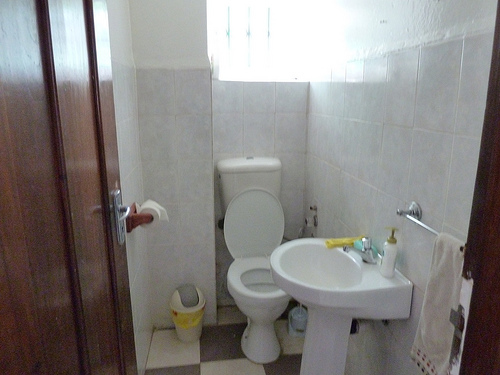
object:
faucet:
[340, 238, 376, 263]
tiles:
[200, 322, 248, 362]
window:
[204, 0, 309, 84]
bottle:
[379, 227, 398, 277]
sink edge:
[321, 234, 407, 287]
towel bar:
[395, 200, 439, 236]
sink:
[271, 238, 410, 321]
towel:
[408, 232, 469, 375]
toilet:
[223, 189, 293, 365]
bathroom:
[83, 0, 500, 375]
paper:
[139, 199, 168, 228]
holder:
[126, 203, 152, 232]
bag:
[172, 310, 202, 328]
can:
[168, 283, 206, 344]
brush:
[290, 303, 308, 332]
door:
[3, 0, 139, 375]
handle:
[114, 189, 130, 244]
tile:
[143, 331, 200, 369]